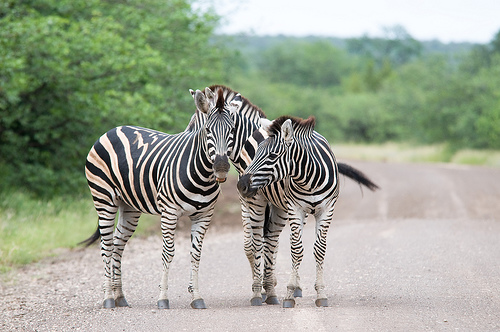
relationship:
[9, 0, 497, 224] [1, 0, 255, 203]
hill covered with trees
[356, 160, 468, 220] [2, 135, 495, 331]
tracks are on road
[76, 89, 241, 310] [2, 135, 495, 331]
zebra in road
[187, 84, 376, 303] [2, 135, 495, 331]
zebra in road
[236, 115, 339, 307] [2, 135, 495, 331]
zebra standing in road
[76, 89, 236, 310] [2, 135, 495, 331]
zebra are in road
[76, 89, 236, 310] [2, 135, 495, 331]
zebra are on road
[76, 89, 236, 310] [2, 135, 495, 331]
zebra are on a street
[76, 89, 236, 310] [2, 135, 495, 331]
zebra are on a road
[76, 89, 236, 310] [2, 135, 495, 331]
zebra are on street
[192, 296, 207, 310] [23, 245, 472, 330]
hoof on ground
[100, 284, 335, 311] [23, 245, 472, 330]
hooves are touching ground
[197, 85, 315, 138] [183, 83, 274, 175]
manes are near to each other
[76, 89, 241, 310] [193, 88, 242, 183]
zebra has a head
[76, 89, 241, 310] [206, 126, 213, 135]
zebra has an eye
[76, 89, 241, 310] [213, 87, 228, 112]
zebra has a mane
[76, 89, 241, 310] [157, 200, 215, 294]
zebra has front legs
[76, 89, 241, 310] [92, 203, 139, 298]
zebra has back legs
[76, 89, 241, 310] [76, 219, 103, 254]
zebra has a tail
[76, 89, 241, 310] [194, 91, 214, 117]
zebra has an ear